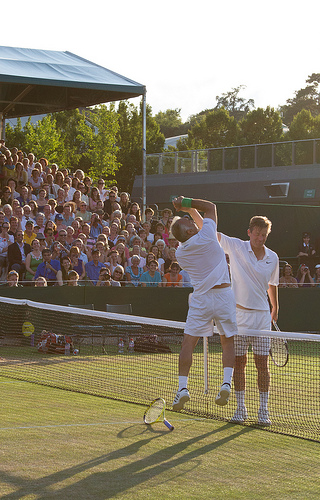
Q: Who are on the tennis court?
A: Tennis players.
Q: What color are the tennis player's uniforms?
A: White.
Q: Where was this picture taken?
A: A tennis court.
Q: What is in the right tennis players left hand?
A: A tennis racket.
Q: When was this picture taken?
A: Daytime.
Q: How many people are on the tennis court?
A: 2.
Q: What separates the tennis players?
A: A net.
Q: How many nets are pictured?
A: 1.